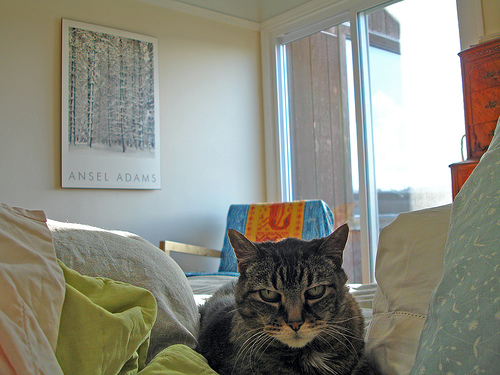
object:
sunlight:
[48, 218, 140, 239]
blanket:
[43, 219, 199, 362]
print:
[67, 169, 160, 183]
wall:
[0, 0, 267, 273]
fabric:
[182, 198, 334, 278]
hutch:
[466, 59, 497, 93]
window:
[363, 0, 466, 240]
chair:
[159, 199, 334, 278]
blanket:
[410, 117, 500, 374]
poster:
[60, 19, 161, 189]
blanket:
[56, 258, 215, 374]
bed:
[0, 273, 500, 373]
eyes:
[303, 283, 330, 300]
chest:
[447, 38, 500, 200]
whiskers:
[230, 325, 285, 374]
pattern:
[442, 317, 480, 331]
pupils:
[303, 287, 324, 296]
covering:
[182, 197, 333, 278]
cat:
[196, 221, 374, 375]